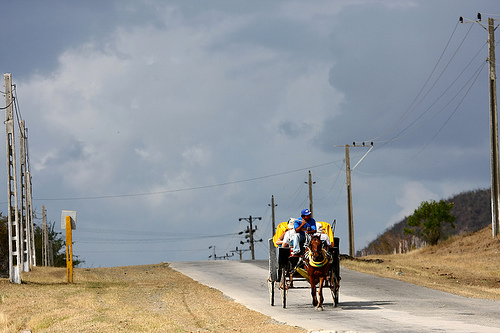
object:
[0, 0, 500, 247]
clouds sky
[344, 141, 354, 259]
pole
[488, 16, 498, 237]
pole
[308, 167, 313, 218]
pole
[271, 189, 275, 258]
pole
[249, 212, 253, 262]
pole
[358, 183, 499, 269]
hillside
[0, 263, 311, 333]
grass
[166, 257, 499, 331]
road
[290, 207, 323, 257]
man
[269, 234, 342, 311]
cart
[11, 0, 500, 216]
cloud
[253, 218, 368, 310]
wagon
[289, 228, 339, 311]
horse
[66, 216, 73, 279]
sign post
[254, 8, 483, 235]
electrical line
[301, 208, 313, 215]
hat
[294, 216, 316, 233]
shirt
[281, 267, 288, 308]
wheel